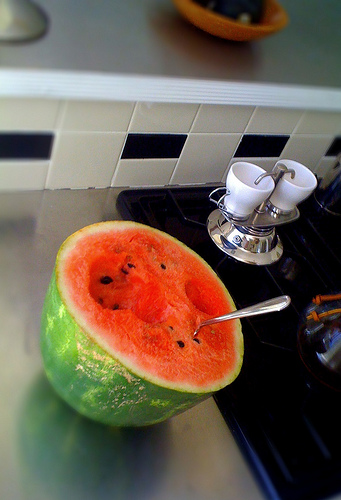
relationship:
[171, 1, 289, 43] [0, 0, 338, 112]
bowl on top of counter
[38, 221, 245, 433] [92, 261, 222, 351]
watermelon has seeds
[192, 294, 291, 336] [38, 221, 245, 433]
fork stuck in watermelon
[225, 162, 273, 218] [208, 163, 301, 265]
cup on top of machine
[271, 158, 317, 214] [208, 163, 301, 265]
cup on top of machine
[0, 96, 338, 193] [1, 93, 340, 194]
tiles on backsplash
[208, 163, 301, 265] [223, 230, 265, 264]
machine has a reflection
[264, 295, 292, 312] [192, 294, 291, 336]
part of a fork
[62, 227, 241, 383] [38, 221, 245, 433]
red of watermelon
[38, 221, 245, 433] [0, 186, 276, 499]
watermelon on top of counter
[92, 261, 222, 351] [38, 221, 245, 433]
seeds inside of a watermelon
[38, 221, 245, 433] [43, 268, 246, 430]
watermelon has rind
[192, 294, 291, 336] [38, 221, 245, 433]
fork in a watermelon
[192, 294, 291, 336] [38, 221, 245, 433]
fork taken out of watermelon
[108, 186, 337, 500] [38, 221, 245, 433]
tray next to watermelon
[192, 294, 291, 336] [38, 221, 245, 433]
fork inside of watermelon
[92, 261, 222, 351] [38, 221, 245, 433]
seeds in watermelon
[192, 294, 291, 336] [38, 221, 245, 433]
fork inside watermelon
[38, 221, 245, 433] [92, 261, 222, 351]
watermelon with seeds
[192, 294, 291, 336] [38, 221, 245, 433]
fork in watermelon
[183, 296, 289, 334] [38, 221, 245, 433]
fork in watermelon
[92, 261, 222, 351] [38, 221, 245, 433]
seeds inside watermelon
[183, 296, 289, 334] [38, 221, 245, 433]
fork inside watermelon